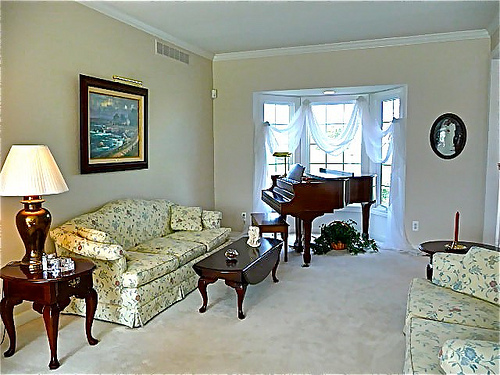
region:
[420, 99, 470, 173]
Picture on a wall.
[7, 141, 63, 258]
Vase with white shade.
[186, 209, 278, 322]
Brown wooden coffee table.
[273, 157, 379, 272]
Brown wooden piano and bench.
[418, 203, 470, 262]
Candle on a table.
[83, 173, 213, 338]
Flower couch on rug.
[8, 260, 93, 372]
Brown wooden side table.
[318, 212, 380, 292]
Green plant on the carpet.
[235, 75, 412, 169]
White cutains in a window.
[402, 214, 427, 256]
White electric plug on wall.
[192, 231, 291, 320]
a dark wood coffee table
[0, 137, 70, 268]
a lamp turned on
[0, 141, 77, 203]
a white lamp shade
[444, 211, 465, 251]
a candle on a candle holder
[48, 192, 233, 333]
sofa with floral print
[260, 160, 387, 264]
piano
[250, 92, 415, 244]
white drapes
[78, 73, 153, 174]
a picture hanging on the wall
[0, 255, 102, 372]
a wooden end table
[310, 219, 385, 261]
a green potted plant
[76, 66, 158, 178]
Painting on living room wall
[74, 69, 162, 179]
Painting has brown frame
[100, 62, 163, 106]
Painting has light above it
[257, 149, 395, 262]
Piano sitting in bay window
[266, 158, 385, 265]
Piano is brown wood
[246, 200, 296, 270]
Piano has matching stool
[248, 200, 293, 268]
Piano stool is brown wood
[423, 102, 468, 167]
Oval shaped photo on wall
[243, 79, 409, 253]
Window has transparent curtains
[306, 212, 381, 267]
Brown basket of greenery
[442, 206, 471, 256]
A RED CANDLE IN A CANDLE-HOLDER ON A TABLE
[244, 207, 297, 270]
A BROWN PIANO BENCH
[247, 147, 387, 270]
A BROWN PIANO AND BROWN PIANO BENCH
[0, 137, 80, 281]
A GOLD LAMP BODY WITH A WHITE LAMP SHADE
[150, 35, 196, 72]
AN AIR-CONDITIONING VENT ON THE WALL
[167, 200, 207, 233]
A COUCH PILLOW WITH A FLORAL PATTERN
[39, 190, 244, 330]
A COUCH WITH A FLORAL DESIGN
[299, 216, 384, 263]
A GREEN PLANT IN A BROWN BASKET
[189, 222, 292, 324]
A BROWN TABLE WITH DECORATIVE ITEMS ON TOP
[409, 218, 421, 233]
A WALL OUTLET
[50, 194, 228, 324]
couch with floral design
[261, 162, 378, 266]
piano in front of window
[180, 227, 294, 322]
coffee table in front of couch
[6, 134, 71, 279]
lamp on end table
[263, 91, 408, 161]
curtain hanging from window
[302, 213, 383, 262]
plant on floor under piano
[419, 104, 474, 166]
picture in oval frame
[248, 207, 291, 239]
shiny bench in front of piano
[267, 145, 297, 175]
lamp on top of piano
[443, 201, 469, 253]
candle in holder on table